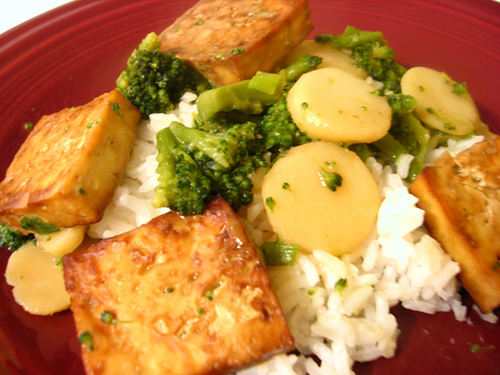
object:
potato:
[259, 138, 381, 261]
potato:
[284, 65, 392, 146]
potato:
[398, 61, 482, 141]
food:
[0, 0, 499, 373]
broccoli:
[317, 166, 345, 192]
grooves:
[0, 0, 189, 124]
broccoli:
[152, 120, 263, 217]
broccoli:
[115, 30, 211, 116]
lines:
[2, 0, 152, 77]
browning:
[201, 218, 261, 277]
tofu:
[61, 193, 297, 373]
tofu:
[153, 0, 313, 83]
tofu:
[2, 89, 147, 235]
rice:
[75, 56, 487, 372]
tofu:
[408, 129, 500, 317]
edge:
[0, 0, 82, 40]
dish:
[0, 0, 499, 375]